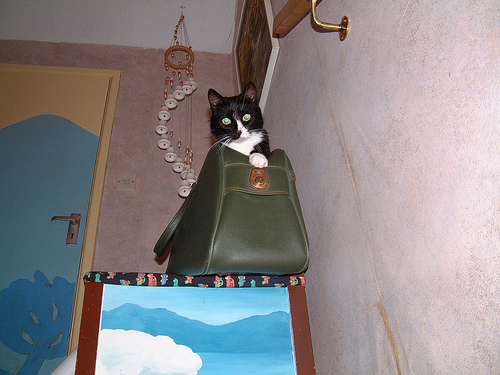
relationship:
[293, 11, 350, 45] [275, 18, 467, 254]
fixture on wall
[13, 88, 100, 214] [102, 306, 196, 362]
mountain and cloud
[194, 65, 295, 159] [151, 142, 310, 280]
cat in bag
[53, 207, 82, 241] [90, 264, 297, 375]
handle on door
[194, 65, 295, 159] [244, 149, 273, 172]
cat has foot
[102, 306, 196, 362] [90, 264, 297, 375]
cloud in picture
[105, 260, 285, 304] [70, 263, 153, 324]
blanket on table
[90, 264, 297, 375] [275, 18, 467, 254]
door on wall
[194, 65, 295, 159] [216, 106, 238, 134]
cat has eye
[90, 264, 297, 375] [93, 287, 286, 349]
picture of scenery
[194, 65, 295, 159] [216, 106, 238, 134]
cat with eye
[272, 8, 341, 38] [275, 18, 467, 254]
lamp on wall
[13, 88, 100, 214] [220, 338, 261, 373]
mountain and water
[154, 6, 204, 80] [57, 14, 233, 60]
object in ceiling